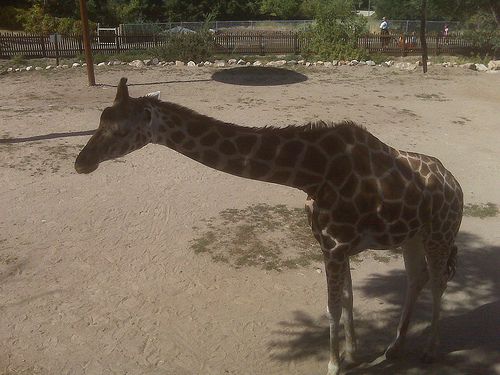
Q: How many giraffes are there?
A: One.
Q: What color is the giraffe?
A: Brown.